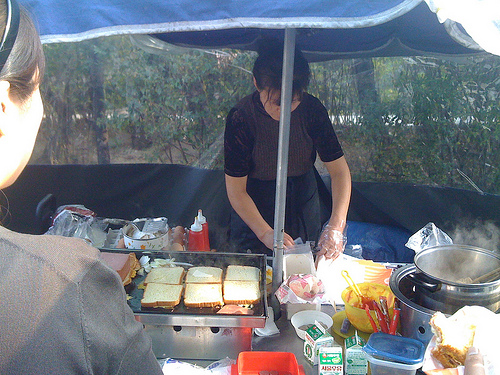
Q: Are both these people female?
A: Yes, all the people are female.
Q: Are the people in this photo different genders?
A: No, all the people are female.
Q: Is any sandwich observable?
A: Yes, there is a sandwich.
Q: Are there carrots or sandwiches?
A: Yes, there is a sandwich.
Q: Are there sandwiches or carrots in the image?
A: Yes, there is a sandwich.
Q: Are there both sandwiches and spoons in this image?
A: No, there is a sandwich but no spoons.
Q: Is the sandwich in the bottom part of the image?
A: Yes, the sandwich is in the bottom of the image.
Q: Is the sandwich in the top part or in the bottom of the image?
A: The sandwich is in the bottom of the image.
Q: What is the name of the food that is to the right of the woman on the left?
A: The food is a sandwich.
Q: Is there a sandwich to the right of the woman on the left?
A: Yes, there is a sandwich to the right of the woman.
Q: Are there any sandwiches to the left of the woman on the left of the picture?
A: No, the sandwich is to the right of the woman.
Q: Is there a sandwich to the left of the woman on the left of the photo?
A: No, the sandwich is to the right of the woman.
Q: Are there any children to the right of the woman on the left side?
A: No, there is a sandwich to the right of the woman.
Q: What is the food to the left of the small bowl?
A: The food is a sandwich.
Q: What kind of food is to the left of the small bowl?
A: The food is a sandwich.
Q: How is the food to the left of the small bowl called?
A: The food is a sandwich.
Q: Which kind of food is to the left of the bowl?
A: The food is a sandwich.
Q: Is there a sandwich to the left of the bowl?
A: Yes, there is a sandwich to the left of the bowl.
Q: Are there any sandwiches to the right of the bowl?
A: No, the sandwich is to the left of the bowl.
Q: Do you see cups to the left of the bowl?
A: No, there is a sandwich to the left of the bowl.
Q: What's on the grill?
A: The sandwich is on the grill.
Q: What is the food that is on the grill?
A: The food is a sandwich.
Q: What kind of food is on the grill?
A: The food is a sandwich.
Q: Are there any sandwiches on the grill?
A: Yes, there is a sandwich on the grill.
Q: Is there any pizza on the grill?
A: No, there is a sandwich on the grill.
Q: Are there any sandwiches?
A: Yes, there is a sandwich.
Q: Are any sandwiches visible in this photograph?
A: Yes, there is a sandwich.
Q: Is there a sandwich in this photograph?
A: Yes, there is a sandwich.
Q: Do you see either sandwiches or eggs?
A: Yes, there is a sandwich.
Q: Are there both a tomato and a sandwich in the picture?
A: No, there is a sandwich but no tomatoes.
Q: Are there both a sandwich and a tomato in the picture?
A: No, there is a sandwich but no tomatoes.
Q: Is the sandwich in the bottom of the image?
A: Yes, the sandwich is in the bottom of the image.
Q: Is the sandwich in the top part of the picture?
A: No, the sandwich is in the bottom of the image.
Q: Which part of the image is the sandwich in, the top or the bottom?
A: The sandwich is in the bottom of the image.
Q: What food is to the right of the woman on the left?
A: The food is a sandwich.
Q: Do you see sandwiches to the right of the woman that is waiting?
A: Yes, there is a sandwich to the right of the woman.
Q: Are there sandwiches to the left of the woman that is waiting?
A: No, the sandwich is to the right of the woman.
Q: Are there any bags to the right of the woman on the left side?
A: No, there is a sandwich to the right of the woman.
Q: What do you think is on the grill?
A: The sandwich is on the grill.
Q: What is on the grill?
A: The sandwich is on the grill.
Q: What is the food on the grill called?
A: The food is a sandwich.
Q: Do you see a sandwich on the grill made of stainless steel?
A: Yes, there is a sandwich on the grill.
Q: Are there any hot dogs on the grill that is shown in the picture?
A: No, there is a sandwich on the grill.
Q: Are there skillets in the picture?
A: No, there are no skillets.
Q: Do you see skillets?
A: No, there are no skillets.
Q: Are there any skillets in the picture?
A: No, there are no skillets.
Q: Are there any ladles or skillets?
A: No, there are no skillets or ladles.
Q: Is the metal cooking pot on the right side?
A: Yes, the cooking pot is on the right of the image.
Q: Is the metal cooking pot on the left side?
A: No, the cooking pot is on the right of the image.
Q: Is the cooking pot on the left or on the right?
A: The cooking pot is on the right of the image.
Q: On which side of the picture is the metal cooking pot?
A: The cooking pot is on the right of the image.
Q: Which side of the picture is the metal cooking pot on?
A: The cooking pot is on the right of the image.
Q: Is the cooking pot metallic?
A: Yes, the cooking pot is metallic.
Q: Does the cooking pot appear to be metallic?
A: Yes, the cooking pot is metallic.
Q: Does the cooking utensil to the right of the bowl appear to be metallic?
A: Yes, the cooking pot is metallic.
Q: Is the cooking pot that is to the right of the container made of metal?
A: Yes, the cooking pot is made of metal.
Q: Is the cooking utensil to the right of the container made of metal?
A: Yes, the cooking pot is made of metal.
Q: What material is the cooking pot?
A: The cooking pot is made of metal.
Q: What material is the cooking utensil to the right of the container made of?
A: The cooking pot is made of metal.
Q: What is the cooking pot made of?
A: The cooking pot is made of metal.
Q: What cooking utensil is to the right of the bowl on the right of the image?
A: The cooking utensil is a cooking pot.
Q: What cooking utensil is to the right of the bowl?
A: The cooking utensil is a cooking pot.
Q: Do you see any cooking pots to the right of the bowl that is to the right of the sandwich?
A: Yes, there is a cooking pot to the right of the bowl.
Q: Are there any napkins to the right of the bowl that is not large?
A: No, there is a cooking pot to the right of the bowl.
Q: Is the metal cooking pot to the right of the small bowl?
A: Yes, the cooking pot is to the right of the bowl.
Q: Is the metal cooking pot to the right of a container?
A: Yes, the cooking pot is to the right of a container.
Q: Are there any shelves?
A: No, there are no shelves.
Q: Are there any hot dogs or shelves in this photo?
A: No, there are no shelves or hot dogs.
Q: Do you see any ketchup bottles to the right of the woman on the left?
A: Yes, there is a ketchup bottle to the right of the woman.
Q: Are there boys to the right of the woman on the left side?
A: No, there is a ketchup bottle to the right of the woman.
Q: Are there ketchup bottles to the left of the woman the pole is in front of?
A: Yes, there is a ketchup bottle to the left of the woman.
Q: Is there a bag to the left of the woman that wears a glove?
A: No, there is a ketchup bottle to the left of the woman.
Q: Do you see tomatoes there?
A: No, there are no tomatoes.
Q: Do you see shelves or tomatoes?
A: No, there are no tomatoes or shelves.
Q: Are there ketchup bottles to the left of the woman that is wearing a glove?
A: Yes, there is a ketchup bottle to the left of the woman.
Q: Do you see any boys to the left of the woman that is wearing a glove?
A: No, there is a ketchup bottle to the left of the woman.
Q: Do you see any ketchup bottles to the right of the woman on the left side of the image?
A: Yes, there is a ketchup bottle to the right of the woman.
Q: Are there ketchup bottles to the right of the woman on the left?
A: Yes, there is a ketchup bottle to the right of the woman.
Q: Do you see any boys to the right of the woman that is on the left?
A: No, there is a ketchup bottle to the right of the woman.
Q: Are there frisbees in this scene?
A: No, there are no frisbees.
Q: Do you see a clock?
A: No, there are no clocks.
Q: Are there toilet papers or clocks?
A: No, there are no clocks or toilet papers.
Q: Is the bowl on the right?
A: Yes, the bowl is on the right of the image.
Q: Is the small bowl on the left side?
A: No, the bowl is on the right of the image.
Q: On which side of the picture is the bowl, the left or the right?
A: The bowl is on the right of the image.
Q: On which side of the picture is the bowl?
A: The bowl is on the right of the image.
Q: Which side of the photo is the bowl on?
A: The bowl is on the right of the image.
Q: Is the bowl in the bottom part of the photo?
A: Yes, the bowl is in the bottom of the image.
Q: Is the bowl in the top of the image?
A: No, the bowl is in the bottom of the image.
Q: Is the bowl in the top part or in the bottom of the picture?
A: The bowl is in the bottom of the image.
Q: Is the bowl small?
A: Yes, the bowl is small.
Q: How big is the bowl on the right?
A: The bowl is small.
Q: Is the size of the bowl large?
A: No, the bowl is small.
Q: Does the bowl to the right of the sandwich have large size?
A: No, the bowl is small.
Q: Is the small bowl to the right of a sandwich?
A: Yes, the bowl is to the right of a sandwich.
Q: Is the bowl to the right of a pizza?
A: No, the bowl is to the right of a sandwich.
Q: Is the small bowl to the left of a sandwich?
A: No, the bowl is to the right of a sandwich.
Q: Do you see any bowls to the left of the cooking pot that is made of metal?
A: Yes, there is a bowl to the left of the cooking pot.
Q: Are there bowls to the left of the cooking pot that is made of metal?
A: Yes, there is a bowl to the left of the cooking pot.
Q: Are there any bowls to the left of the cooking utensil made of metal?
A: Yes, there is a bowl to the left of the cooking pot.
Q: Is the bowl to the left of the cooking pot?
A: Yes, the bowl is to the left of the cooking pot.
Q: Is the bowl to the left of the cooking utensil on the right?
A: Yes, the bowl is to the left of the cooking pot.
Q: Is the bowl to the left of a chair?
A: No, the bowl is to the left of the cooking pot.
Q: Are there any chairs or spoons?
A: No, there are no chairs or spoons.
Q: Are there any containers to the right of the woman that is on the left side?
A: Yes, there is a container to the right of the woman.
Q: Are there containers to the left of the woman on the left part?
A: No, the container is to the right of the woman.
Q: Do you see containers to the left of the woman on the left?
A: No, the container is to the right of the woman.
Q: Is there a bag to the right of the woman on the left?
A: No, there is a container to the right of the woman.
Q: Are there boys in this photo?
A: No, there are no boys.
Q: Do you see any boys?
A: No, there are no boys.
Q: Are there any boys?
A: No, there are no boys.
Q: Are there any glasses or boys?
A: No, there are no boys or glasses.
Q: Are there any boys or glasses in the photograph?
A: No, there are no boys or glasses.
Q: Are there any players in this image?
A: No, there are no players.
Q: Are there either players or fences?
A: No, there are no players or fences.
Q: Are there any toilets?
A: No, there are no toilets.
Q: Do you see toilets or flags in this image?
A: No, there are no toilets or flags.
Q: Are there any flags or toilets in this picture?
A: No, there are no toilets or flags.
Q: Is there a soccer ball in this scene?
A: No, there are no soccer balls.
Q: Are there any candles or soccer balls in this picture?
A: No, there are no soccer balls or candles.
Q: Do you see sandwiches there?
A: Yes, there is a sandwich.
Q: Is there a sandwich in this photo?
A: Yes, there is a sandwich.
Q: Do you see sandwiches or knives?
A: Yes, there is a sandwich.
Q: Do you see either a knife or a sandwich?
A: Yes, there is a sandwich.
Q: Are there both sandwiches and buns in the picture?
A: No, there is a sandwich but no buns.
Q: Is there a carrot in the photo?
A: No, there are no carrots.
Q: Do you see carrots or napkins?
A: No, there are no carrots or napkins.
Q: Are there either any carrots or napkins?
A: No, there are no carrots or napkins.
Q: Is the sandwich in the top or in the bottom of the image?
A: The sandwich is in the bottom of the image.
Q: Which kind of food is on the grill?
A: The food is a sandwich.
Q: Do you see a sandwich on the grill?
A: Yes, there is a sandwich on the grill.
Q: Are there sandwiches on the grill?
A: Yes, there is a sandwich on the grill.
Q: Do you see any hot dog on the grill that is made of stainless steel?
A: No, there is a sandwich on the grill.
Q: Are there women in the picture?
A: Yes, there is a woman.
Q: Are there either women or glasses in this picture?
A: Yes, there is a woman.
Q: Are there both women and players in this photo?
A: No, there is a woman but no players.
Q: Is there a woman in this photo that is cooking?
A: Yes, there is a woman that is cooking.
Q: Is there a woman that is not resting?
A: Yes, there is a woman that is cooking.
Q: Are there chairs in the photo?
A: No, there are no chairs.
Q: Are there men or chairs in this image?
A: No, there are no chairs or men.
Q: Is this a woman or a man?
A: This is a woman.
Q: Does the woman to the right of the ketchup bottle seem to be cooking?
A: Yes, the woman is cooking.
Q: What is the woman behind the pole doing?
A: The woman is cooking.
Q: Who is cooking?
A: The woman is cooking.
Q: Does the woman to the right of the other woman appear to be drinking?
A: No, the woman is cooking.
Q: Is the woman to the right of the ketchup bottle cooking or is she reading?
A: The woman is cooking.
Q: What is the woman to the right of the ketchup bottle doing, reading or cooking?
A: The woman is cooking.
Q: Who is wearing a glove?
A: The woman is wearing a glove.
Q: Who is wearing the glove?
A: The woman is wearing a glove.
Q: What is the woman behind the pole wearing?
A: The woman is wearing a glove.